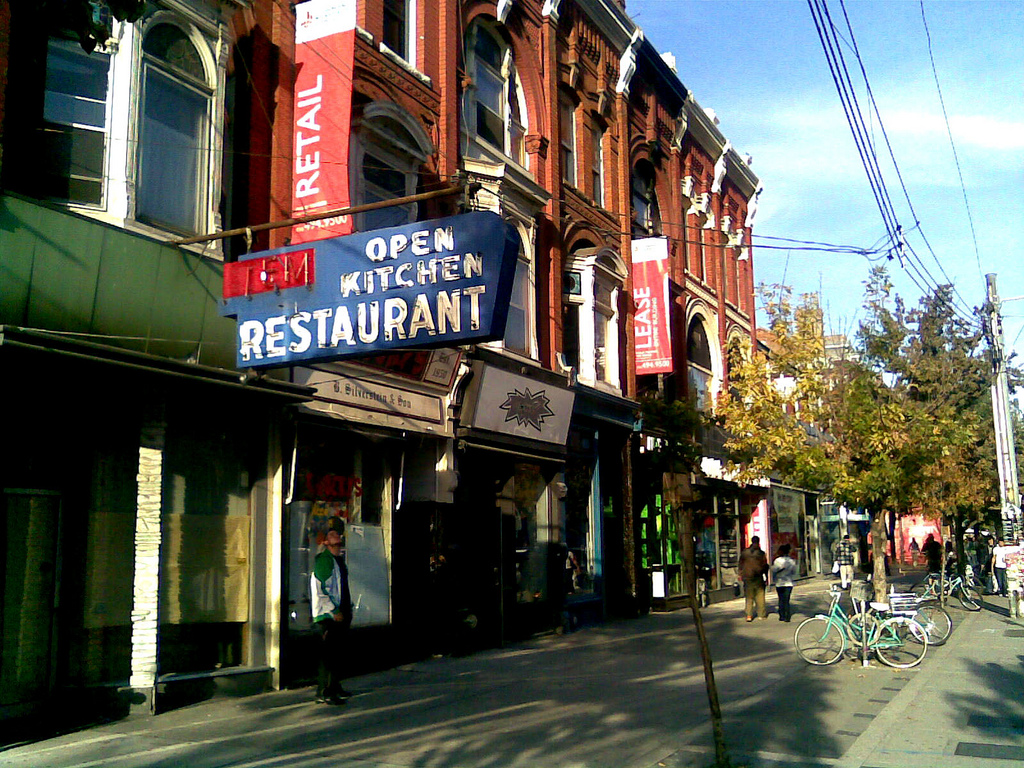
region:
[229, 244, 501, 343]
blue and white sign on the front of the buidling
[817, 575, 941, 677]
bicycles parted on the side of the street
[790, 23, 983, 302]
power lines going down the street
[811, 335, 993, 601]
trees growing on the sidewalk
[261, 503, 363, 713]
person standing on the sidewalk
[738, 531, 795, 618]
people walking down the sidewalk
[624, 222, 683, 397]
red sign on the front of the building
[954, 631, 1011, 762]
shadow on the street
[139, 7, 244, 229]
arched window above the blue and white sign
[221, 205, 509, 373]
Blue and white restaurant sign.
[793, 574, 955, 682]
Bicycles parked on side of street.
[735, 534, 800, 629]
People walking down the sidewalk.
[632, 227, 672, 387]
A red and white banner.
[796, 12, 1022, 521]
Power lines attached to pole.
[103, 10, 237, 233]
Window with a white frame.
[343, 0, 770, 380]
Red bricks and white molding on building.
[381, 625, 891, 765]
Shade from tree leaves.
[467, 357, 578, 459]
White sign attached to building.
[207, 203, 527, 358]
Restaurant neon sign.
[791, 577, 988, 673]
Bicycles parked on the sidewalk.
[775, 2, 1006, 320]
Power lines above the trees.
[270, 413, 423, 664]
Items on display in store window.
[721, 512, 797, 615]
Two people talking.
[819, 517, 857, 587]
Person walking down the sidewalk.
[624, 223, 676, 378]
Lease signage on side of building.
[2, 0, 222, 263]
Second story windows.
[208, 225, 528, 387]
A blue sign hanging from the store.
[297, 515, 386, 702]
A man looking up at the sign.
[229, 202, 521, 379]
The blue business sign mounted to the building.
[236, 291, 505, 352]
The word Restaurant on the blue business sign.